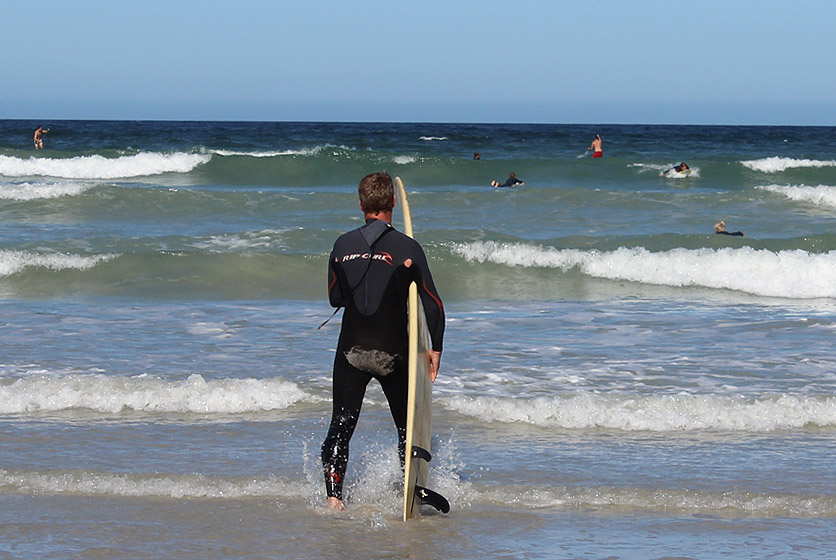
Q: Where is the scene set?
A: At the beach.